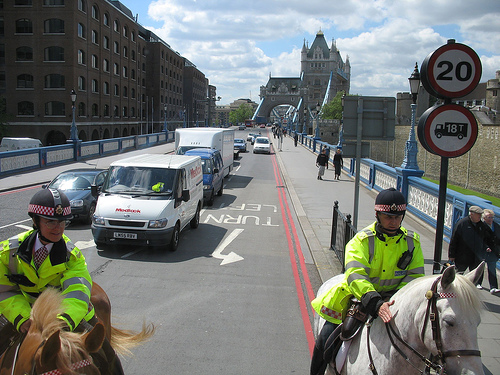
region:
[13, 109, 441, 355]
two cops on patrol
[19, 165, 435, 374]
these officers are riding on horseback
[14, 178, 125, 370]
this cop has a brown horse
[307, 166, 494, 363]
this cop has a white horse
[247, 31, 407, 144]
a busy bridge with pedestrians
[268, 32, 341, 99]
a structure next to the bridge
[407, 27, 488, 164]
traffic sign for vehicles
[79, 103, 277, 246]
traffic on the bridge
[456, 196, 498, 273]
two people walking on the bridge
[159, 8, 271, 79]
clouds in the sky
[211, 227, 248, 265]
An arrow on the street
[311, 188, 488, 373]
A man on a horse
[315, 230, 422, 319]
A neon yellow safety jacket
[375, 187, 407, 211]
A helmet with a badge on it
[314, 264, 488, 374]
A white horse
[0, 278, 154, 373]
A brown horse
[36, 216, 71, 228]
A pair of clear glasses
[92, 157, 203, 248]
A white van driving down the street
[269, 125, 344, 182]
People walking down the sidewalk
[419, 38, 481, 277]
A traffic sign on the sidewalk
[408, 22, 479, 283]
british street sign on sidewalk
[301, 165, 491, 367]
officer riding white horse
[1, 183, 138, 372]
officer riding brown horse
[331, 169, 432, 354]
officer wearing bright green reflective coat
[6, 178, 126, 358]
officer wearing fluorescent green coat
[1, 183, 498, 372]
two officers on horses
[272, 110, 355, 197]
pedestrians walking on sidewalk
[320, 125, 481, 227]
railing on sidewalk painted blue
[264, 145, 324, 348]
double red lines on side of road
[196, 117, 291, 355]
left turn only lane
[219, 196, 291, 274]
the arrow says turn left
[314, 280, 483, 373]
the horse is white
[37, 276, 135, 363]
the horse is brown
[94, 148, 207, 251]
the van is white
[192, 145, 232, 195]
the car is blue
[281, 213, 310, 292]
the two lines are red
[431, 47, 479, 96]
the spped is 20 miles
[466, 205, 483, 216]
the hat is brown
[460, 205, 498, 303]
the two people are old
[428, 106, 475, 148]
the sign says only 18T TRUCK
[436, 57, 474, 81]
The number 20 on the sign.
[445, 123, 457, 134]
The number 18 on the sign.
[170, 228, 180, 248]
The front wheel of the white van.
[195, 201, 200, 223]
The back tire of the van.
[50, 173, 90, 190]
The front window of the car on the left of the van.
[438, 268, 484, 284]
The ears of the white horse.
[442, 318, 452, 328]
The eye of the white horse.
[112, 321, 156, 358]
The tail of the brown horse.